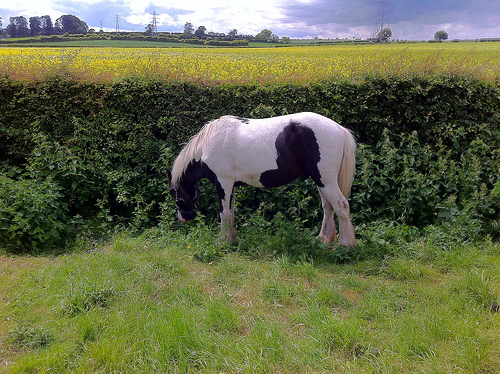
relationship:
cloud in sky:
[126, 3, 307, 36] [2, 3, 500, 38]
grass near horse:
[0, 221, 499, 373] [166, 111, 359, 258]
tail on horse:
[339, 128, 358, 201] [166, 111, 359, 258]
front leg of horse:
[219, 178, 232, 246] [166, 111, 359, 258]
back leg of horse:
[319, 179, 355, 247] [166, 111, 359, 258]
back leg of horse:
[317, 186, 337, 244] [166, 111, 359, 258]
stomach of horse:
[239, 173, 308, 187] [166, 111, 359, 258]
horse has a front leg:
[166, 111, 359, 258] [219, 178, 232, 246]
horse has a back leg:
[166, 111, 359, 258] [317, 186, 337, 244]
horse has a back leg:
[166, 111, 359, 258] [319, 179, 355, 247]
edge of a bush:
[488, 83, 500, 137] [1, 73, 499, 157]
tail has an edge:
[339, 128, 358, 201] [348, 131, 360, 173]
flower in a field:
[90, 60, 96, 72] [2, 41, 499, 85]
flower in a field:
[149, 63, 153, 69] [2, 41, 499, 85]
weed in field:
[56, 62, 75, 84] [2, 41, 499, 85]